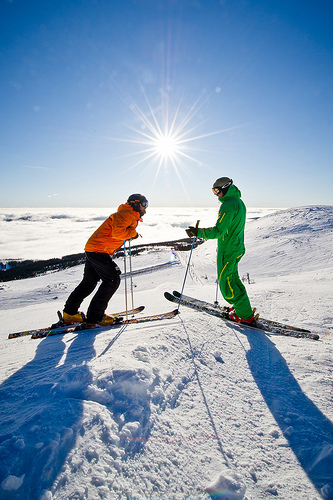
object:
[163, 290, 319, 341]
ski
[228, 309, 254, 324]
foot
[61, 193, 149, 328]
man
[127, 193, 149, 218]
hat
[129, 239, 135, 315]
pole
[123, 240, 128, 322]
pole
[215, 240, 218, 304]
pole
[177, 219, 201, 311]
pole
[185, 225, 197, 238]
hand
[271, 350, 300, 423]
ground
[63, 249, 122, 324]
pants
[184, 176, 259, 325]
people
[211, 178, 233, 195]
goggles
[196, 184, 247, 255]
jacket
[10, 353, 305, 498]
snow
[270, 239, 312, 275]
snow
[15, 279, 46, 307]
ground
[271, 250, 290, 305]
ground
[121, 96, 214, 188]
sun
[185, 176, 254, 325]
man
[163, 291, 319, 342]
skis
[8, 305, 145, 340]
skis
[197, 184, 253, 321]
coveralls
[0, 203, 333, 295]
mountain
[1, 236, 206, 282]
trees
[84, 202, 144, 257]
jacket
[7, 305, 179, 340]
ski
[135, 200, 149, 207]
goggles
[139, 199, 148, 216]
face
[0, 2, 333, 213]
sky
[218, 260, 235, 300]
trim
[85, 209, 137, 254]
body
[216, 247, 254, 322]
pants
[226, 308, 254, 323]
ski boots